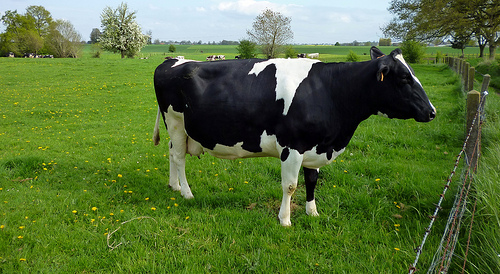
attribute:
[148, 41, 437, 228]
cow — black , white , tagged, black and white, Holstein, milking, healthy, heifer, large, milk, marked, idle, standing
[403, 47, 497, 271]
fence — wired, metal, wooden posted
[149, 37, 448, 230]
white bowl — markings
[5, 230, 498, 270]
pasture — green, are black and white, grassy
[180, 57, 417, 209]
cow — milk, patient, long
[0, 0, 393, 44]
sky — blue, gray, bright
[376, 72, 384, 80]
tag — metal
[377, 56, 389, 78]
ear — black, small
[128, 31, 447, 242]
cow — black and white, tagged, pondering, fenced-in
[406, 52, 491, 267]
fence — barbed-wire, long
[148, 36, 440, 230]
striped sheet — black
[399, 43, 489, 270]
wire — stranded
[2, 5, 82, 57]
trees — are green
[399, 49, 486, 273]
fence — posted, taut, sharp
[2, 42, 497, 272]
pasture — lush, green, dandelion speckled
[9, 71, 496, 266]
field — green  , grassy  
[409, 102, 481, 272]
barbed wire — sharp, dangerous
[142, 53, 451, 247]
cow — black  , white  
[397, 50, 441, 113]
line — white  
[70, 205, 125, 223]
dandelions — are delicate, are hardy, are small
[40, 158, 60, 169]
dandelions — are delicate, are hardy, are small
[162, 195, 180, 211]
dandelions — are delicate, are hardy, are small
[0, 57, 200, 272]
grass — plush, green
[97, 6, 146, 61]
tree — big, agile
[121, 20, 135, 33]
flowers — tiny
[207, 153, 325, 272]
grass — short, green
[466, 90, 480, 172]
post — wooden  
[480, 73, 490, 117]
post — wooden  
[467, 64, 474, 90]
post — wooden  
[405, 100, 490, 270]
fence — wired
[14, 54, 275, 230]
field — green, speckled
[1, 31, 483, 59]
horizon — all-encompassing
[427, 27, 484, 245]
fence — barbed-wire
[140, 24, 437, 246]
cow — adult, black and white, tagged, marked, beautiful, healthy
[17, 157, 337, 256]
grass — short, thick, green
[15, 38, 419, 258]
field — large, grassy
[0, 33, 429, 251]
field — fenced-in, green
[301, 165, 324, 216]
leg — black 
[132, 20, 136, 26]
blooms — white  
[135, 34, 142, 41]
blooms — white  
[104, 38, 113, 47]
blooms — white  